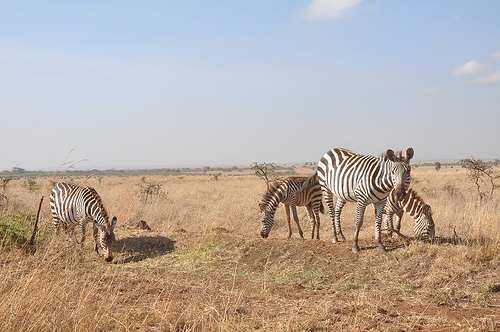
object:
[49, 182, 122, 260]
zebra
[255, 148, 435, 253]
zebras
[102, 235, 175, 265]
shadow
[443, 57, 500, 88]
cloud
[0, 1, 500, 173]
sky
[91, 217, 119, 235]
ears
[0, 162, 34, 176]
mountain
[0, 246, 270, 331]
grass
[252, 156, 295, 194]
tree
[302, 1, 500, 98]
clouds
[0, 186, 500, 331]
field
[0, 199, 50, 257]
grass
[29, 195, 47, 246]
branch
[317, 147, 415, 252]
zebra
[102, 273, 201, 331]
dirt